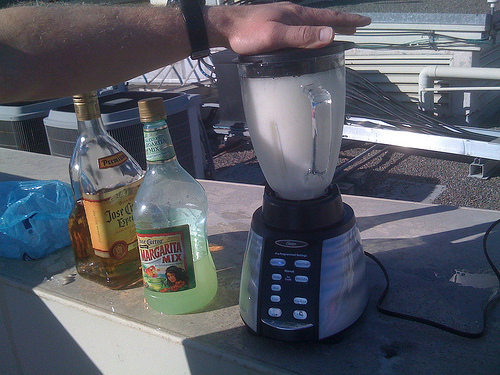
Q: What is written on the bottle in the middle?
A: Margarita Mix.